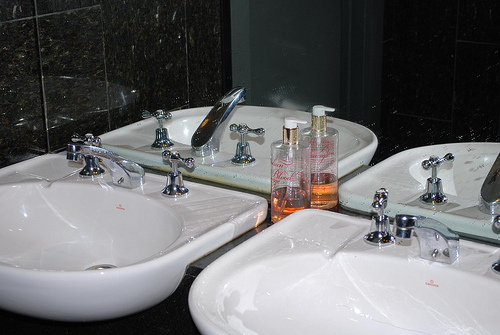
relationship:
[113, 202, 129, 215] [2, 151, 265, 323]
letters on sink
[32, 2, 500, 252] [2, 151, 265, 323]
mirror behind sink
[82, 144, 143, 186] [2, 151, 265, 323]
faucet for sink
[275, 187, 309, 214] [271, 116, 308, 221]
soap in bottle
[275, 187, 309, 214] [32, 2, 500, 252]
soap reflected in mirror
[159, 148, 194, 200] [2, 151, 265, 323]
handle of sink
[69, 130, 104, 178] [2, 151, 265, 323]
handle on sink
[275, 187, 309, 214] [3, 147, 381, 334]
soap on top of counter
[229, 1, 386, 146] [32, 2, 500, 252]
door reflected in mirror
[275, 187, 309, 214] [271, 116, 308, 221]
soap at bottom of bottle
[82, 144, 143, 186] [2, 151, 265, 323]
faucet on sink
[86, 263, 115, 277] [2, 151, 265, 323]
sink drain inside sink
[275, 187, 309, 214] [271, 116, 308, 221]
soap inside bottle